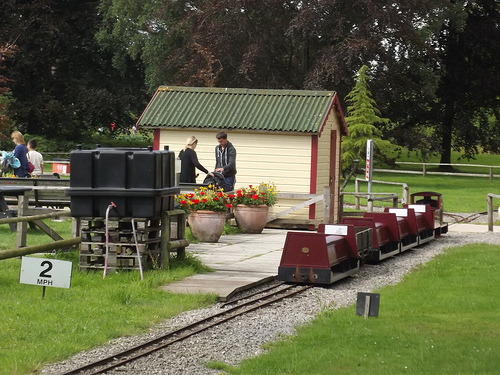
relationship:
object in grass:
[354, 290, 382, 318] [206, 240, 498, 372]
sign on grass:
[17, 251, 74, 290] [1, 215, 226, 373]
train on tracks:
[277, 191, 449, 285] [131, 259, 303, 372]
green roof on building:
[138, 75, 334, 130] [133, 86, 348, 222]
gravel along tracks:
[190, 293, 335, 359] [48, 197, 499, 372]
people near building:
[213, 129, 238, 192] [133, 85, 349, 223]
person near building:
[168, 132, 210, 187] [133, 85, 349, 223]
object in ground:
[338, 276, 405, 321] [2, 124, 497, 372]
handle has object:
[350, 292, 382, 322] [351, 285, 382, 322]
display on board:
[35, 255, 53, 289] [20, 252, 101, 307]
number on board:
[30, 244, 81, 301] [21, 253, 75, 288]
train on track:
[247, 159, 462, 293] [65, 206, 470, 371]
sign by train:
[17, 251, 74, 290] [278, 191, 448, 287]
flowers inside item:
[177, 180, 274, 210] [185, 208, 226, 245]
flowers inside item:
[177, 180, 274, 210] [184, 206, 235, 246]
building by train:
[133, 86, 348, 222] [267, 187, 450, 284]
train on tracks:
[277, 191, 449, 285] [191, 322, 216, 334]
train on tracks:
[277, 191, 449, 285] [189, 313, 205, 328]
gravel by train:
[35, 232, 500, 374] [267, 182, 454, 290]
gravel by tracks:
[35, 232, 500, 374] [48, 197, 499, 372]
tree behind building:
[169, 0, 389, 92] [133, 86, 348, 222]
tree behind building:
[184, 3, 404, 141] [133, 86, 348, 222]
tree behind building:
[71, 0, 170, 75] [133, 86, 348, 222]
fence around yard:
[339, 132, 488, 207] [343, 140, 498, 216]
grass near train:
[206, 240, 498, 372] [278, 191, 448, 287]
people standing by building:
[177, 129, 234, 192] [143, 81, 345, 218]